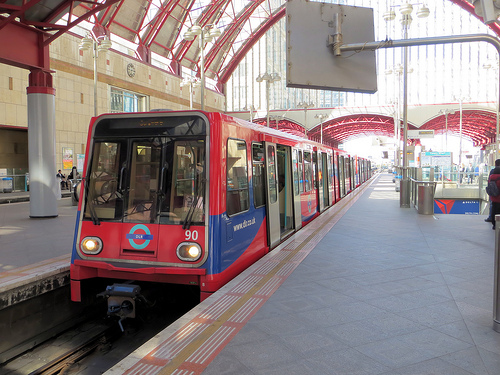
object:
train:
[69, 107, 379, 333]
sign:
[285, 0, 378, 94]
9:
[185, 230, 192, 241]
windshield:
[82, 115, 207, 226]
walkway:
[0, 189, 77, 293]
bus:
[85, 110, 406, 297]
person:
[483, 158, 500, 223]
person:
[67, 166, 82, 192]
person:
[56, 169, 69, 190]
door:
[262, 140, 303, 253]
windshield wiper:
[181, 177, 206, 231]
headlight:
[175, 238, 202, 261]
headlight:
[77, 232, 103, 255]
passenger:
[484, 157, 498, 221]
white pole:
[26, 92, 60, 220]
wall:
[223, 0, 499, 133]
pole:
[339, 32, 500, 56]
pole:
[399, 28, 410, 209]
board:
[285, 0, 378, 95]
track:
[26, 324, 126, 374]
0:
[191, 230, 198, 241]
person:
[485, 166, 500, 230]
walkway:
[100, 171, 500, 375]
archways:
[418, 108, 499, 147]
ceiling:
[0, 0, 499, 148]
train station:
[0, 0, 500, 375]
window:
[82, 117, 205, 226]